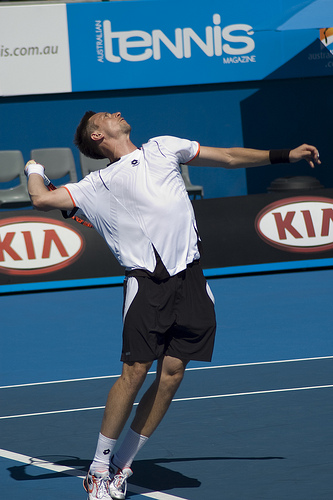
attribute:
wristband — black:
[265, 145, 290, 162]